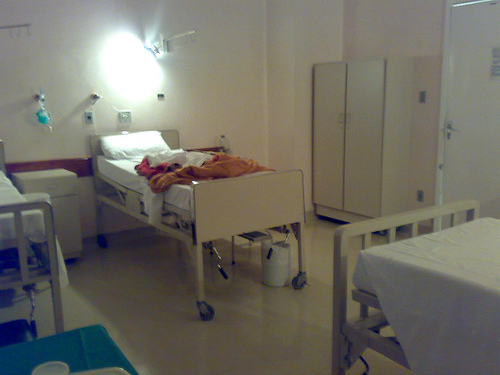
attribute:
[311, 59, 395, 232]
cabinet — beige, white, closed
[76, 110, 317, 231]
bed — white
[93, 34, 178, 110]
circle — on, white, over bed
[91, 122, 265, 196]
view — partial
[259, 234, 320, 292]
object — white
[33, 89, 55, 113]
object — hanging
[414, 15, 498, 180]
door — white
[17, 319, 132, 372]
cloth — blue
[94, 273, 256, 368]
floor — white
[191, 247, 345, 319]
wheels — round, black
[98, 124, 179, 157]
pillow — white, on bed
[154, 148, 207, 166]
sheet — white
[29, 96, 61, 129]
iv — blue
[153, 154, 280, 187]
blanket — orange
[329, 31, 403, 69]
area — locked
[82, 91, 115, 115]
stand — in room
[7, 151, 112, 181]
stripe — red